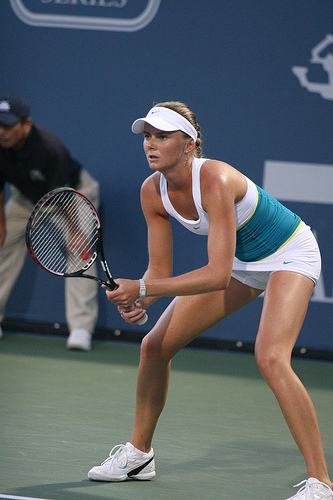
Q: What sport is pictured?
A: Tennis.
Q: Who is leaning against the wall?
A: An official.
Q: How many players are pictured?
A: One.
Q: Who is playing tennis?
A: The woman.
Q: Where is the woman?
A: On the court.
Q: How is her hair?
A: In a ponytail.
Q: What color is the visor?
A: White.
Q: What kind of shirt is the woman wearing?
A: A tank top.